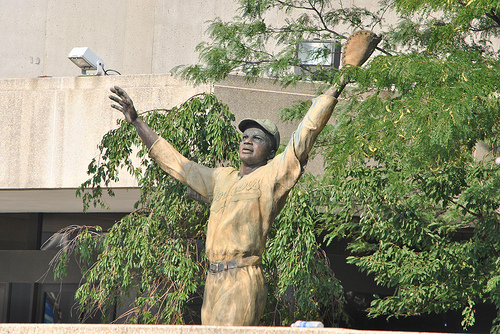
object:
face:
[239, 135, 270, 159]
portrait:
[108, 29, 381, 326]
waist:
[205, 243, 264, 267]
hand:
[109, 85, 155, 146]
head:
[239, 118, 281, 166]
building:
[0, 0, 500, 334]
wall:
[0, 74, 211, 190]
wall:
[5, 0, 151, 42]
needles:
[38, 227, 87, 274]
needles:
[135, 294, 181, 321]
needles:
[360, 298, 411, 314]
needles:
[362, 229, 443, 254]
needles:
[401, 97, 445, 139]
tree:
[190, 0, 500, 314]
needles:
[205, 60, 236, 76]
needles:
[180, 104, 217, 136]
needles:
[410, 3, 454, 31]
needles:
[202, 19, 225, 36]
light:
[67, 47, 104, 76]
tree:
[41, 91, 347, 327]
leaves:
[76, 180, 88, 198]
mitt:
[341, 29, 382, 71]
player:
[108, 30, 383, 328]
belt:
[209, 256, 262, 275]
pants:
[200, 263, 268, 329]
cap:
[236, 118, 280, 152]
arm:
[107, 84, 210, 204]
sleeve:
[148, 136, 217, 204]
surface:
[3, 80, 403, 199]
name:
[210, 179, 261, 213]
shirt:
[148, 94, 339, 261]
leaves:
[78, 238, 93, 264]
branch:
[44, 225, 104, 254]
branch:
[117, 106, 176, 121]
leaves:
[103, 126, 126, 158]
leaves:
[194, 99, 208, 111]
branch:
[174, 92, 205, 119]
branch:
[154, 280, 170, 300]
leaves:
[134, 294, 154, 302]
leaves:
[281, 254, 291, 274]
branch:
[290, 215, 296, 251]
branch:
[301, 187, 348, 206]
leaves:
[304, 192, 324, 205]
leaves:
[374, 215, 399, 246]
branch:
[382, 234, 450, 289]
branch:
[321, 128, 366, 168]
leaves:
[337, 112, 350, 129]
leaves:
[211, 66, 230, 79]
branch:
[197, 48, 277, 81]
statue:
[106, 69, 357, 326]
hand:
[340, 68, 359, 83]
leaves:
[425, 179, 469, 219]